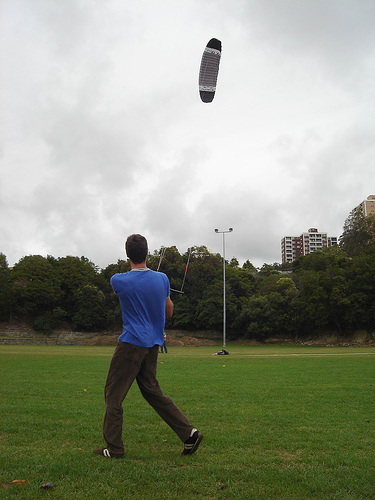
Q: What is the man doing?
A: Flying a kite.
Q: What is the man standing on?
A: Grass.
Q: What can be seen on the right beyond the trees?
A: Buildings.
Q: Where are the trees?
A: Lining the park.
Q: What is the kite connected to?
A: String.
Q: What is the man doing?
A: Flying a kite.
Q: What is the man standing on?
A: Grass.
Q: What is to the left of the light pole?
A: A person.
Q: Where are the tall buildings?
A: Behind the trees on the right.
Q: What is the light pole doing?
A: It is turned off.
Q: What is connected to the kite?
A: String.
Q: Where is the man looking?
A: In the air at the kite.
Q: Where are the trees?
A: On the far side of the park.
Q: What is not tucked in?
A: The man's blue shirt.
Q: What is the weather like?
A: Cloudy and overcast.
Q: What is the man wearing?
A: A pair of men's brown jeans.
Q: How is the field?
A: Green gassy.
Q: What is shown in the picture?
A: A line of green trees.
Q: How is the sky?
A: Cloudy white.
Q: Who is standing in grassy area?
A: A person.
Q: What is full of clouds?
A: The sky.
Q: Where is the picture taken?
A: A park.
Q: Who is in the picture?
A: A man.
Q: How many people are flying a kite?
A: One.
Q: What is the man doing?
A: Flying a kite.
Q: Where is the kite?
A: The air.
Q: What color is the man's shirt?
A: Blue.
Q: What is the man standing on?
A: Grass.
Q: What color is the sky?
A: Gray.